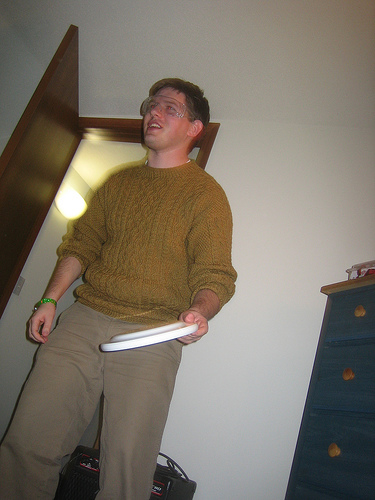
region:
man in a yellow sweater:
[34, 63, 232, 352]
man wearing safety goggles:
[119, 45, 229, 220]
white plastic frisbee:
[101, 316, 199, 360]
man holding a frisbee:
[15, 47, 224, 498]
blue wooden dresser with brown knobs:
[272, 257, 370, 497]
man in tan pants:
[41, 63, 195, 491]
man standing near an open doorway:
[53, 41, 219, 428]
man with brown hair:
[102, 65, 233, 196]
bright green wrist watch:
[25, 293, 60, 313]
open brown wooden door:
[0, 10, 104, 184]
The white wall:
[220, 406, 238, 484]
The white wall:
[226, 427, 236, 480]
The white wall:
[216, 436, 240, 494]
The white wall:
[232, 459, 245, 492]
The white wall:
[229, 448, 252, 498]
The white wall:
[210, 451, 234, 497]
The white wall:
[222, 468, 240, 498]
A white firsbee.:
[97, 320, 200, 356]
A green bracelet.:
[26, 294, 60, 311]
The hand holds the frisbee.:
[176, 306, 210, 351]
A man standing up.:
[0, 52, 242, 498]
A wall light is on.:
[55, 180, 92, 222]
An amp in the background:
[57, 442, 196, 499]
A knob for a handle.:
[322, 439, 342, 459]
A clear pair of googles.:
[135, 95, 208, 124]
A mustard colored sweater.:
[66, 153, 236, 334]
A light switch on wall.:
[9, 270, 28, 298]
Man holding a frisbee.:
[9, 39, 256, 486]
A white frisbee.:
[87, 313, 214, 354]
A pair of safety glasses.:
[129, 66, 217, 160]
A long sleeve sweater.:
[55, 149, 243, 324]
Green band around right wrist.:
[30, 286, 60, 315]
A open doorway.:
[4, 46, 208, 444]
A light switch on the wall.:
[12, 269, 28, 300]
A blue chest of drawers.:
[272, 272, 373, 498]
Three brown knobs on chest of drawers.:
[324, 298, 365, 473]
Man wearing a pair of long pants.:
[5, 68, 250, 494]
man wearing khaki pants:
[123, 437, 135, 465]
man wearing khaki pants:
[119, 443, 132, 464]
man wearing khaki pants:
[109, 427, 141, 469]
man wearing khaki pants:
[132, 442, 142, 465]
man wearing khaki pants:
[113, 426, 129, 451]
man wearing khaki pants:
[110, 444, 131, 468]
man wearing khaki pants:
[126, 468, 139, 492]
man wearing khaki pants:
[134, 460, 145, 480]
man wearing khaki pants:
[126, 451, 138, 468]